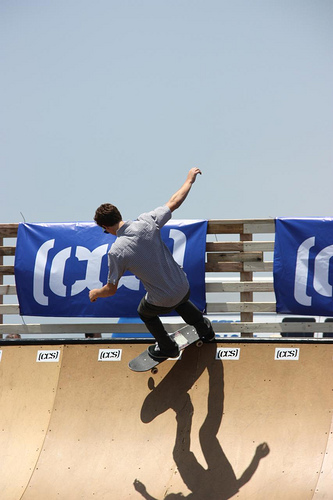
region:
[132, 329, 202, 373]
black skate board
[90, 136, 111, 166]
white snow on hill side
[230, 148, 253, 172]
white snow on hill side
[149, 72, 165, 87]
white snow on hill side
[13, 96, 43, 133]
white snow on hill side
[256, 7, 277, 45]
white snow on hill side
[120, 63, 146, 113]
white snow on hill side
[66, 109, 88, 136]
white snow on hill side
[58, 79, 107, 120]
white snow on hill side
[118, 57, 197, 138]
white snow on hill side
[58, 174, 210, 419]
young man doing trick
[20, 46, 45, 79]
white clouds in blue sky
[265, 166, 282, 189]
white clouds in blue sky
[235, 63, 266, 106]
white clouds in blue sky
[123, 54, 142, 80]
white clouds in blue sky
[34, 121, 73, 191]
white clouds in blue sky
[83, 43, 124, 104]
white clouds in blue sky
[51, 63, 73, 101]
white clouds in blue sky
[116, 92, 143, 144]
white clouds in blue sky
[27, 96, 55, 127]
white clouds in blue sky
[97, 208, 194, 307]
Light blue short-sleeved cotton shirt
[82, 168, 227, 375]
A man riding his skateboard on a skateboard ramp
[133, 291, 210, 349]
Back of a pair of mens black jeans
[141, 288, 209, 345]
Pair of mens black jeans as viewed from the back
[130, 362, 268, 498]
The shadow of a person skateboarding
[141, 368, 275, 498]
A shadow of a person riding a skateboard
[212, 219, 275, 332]
Weathered wooden fencing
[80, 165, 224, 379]
A skateboarder wearing sunglasses in action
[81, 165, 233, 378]
A skateboarder in action on the halfpipe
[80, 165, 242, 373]
A man skateboarding on a halfpipe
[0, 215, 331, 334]
Some wooden railing atop a ramp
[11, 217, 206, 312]
A large blue and white banner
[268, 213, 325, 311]
A large blue and white banner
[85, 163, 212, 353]
a person riding a skateboard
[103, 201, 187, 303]
a grey t-shirt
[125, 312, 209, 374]
a skateboard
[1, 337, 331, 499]
A large wooden ramp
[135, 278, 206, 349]
a pair of black pants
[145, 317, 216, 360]
A pair of black shoes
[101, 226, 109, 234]
a pair of sunglasses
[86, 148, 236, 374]
a man skateboarding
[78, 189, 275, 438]
a man riding a skateboard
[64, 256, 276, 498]
a shadow of a man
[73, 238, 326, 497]
a man and skateboarders shadow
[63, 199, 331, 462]
a shadow of a skateboarder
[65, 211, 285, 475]
a man on a ramp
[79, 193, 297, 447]
a man skateboarding on a ramp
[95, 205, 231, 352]
a man wearing shirtsi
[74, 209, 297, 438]
a man wearing jeans